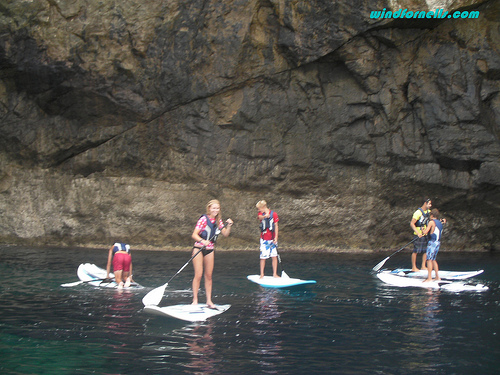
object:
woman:
[187, 198, 235, 314]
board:
[142, 302, 232, 322]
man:
[409, 196, 445, 274]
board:
[391, 267, 483, 279]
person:
[103, 239, 135, 289]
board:
[74, 262, 146, 292]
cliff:
[0, 0, 496, 249]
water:
[0, 251, 497, 371]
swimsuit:
[191, 216, 220, 256]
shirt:
[257, 211, 279, 242]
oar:
[141, 220, 231, 308]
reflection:
[252, 286, 280, 337]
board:
[243, 273, 316, 288]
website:
[367, 7, 479, 20]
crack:
[43, 0, 496, 168]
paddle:
[365, 232, 426, 275]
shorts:
[110, 250, 133, 271]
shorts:
[258, 237, 279, 261]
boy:
[252, 200, 280, 279]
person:
[417, 208, 443, 284]